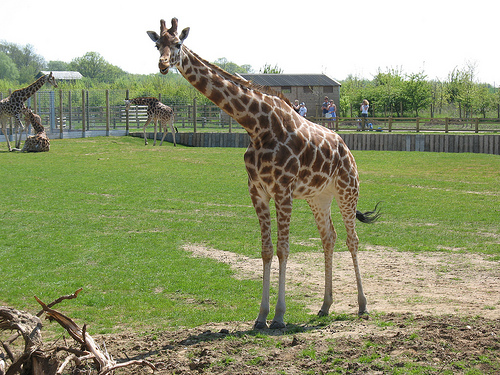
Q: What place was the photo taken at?
A: It was taken at the park.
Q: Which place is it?
A: It is a park.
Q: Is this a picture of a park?
A: Yes, it is showing a park.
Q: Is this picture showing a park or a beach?
A: It is showing a park.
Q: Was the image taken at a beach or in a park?
A: It was taken at a park.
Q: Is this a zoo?
A: No, it is a park.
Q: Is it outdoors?
A: Yes, it is outdoors.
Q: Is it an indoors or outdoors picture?
A: It is outdoors.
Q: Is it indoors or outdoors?
A: It is outdoors.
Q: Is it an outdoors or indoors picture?
A: It is outdoors.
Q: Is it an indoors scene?
A: No, it is outdoors.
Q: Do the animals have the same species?
A: Yes, all the animals are giraffes.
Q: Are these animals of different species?
A: No, all the animals are giraffes.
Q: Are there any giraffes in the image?
A: Yes, there is a giraffe.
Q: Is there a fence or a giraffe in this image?
A: Yes, there is a giraffe.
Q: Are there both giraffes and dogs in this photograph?
A: No, there is a giraffe but no dogs.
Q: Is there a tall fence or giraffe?
A: Yes, there is a tall giraffe.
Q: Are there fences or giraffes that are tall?
A: Yes, the giraffe is tall.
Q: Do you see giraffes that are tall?
A: Yes, there is a tall giraffe.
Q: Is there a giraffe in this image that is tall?
A: Yes, there is a giraffe that is tall.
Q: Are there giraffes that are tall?
A: Yes, there is a giraffe that is tall.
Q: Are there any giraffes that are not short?
A: Yes, there is a tall giraffe.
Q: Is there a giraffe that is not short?
A: Yes, there is a tall giraffe.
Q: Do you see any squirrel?
A: No, there are no squirrels.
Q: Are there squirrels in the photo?
A: No, there are no squirrels.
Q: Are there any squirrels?
A: No, there are no squirrels.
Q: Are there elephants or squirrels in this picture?
A: No, there are no squirrels or elephants.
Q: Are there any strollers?
A: No, there are no strollers.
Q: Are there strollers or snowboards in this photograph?
A: No, there are no strollers or snowboards.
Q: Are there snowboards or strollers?
A: No, there are no strollers or snowboards.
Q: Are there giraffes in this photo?
A: Yes, there is a giraffe.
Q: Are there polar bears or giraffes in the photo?
A: Yes, there is a giraffe.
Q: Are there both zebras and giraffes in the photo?
A: No, there is a giraffe but no zebras.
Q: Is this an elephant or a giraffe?
A: This is a giraffe.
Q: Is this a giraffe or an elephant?
A: This is a giraffe.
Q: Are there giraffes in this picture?
A: Yes, there are giraffes.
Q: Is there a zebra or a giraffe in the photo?
A: Yes, there are giraffes.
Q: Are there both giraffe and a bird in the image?
A: No, there are giraffes but no birds.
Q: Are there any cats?
A: No, there are no cats.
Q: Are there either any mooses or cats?
A: No, there are no cats or mooses.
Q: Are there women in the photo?
A: Yes, there is a woman.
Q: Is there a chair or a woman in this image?
A: Yes, there is a woman.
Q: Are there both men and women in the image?
A: No, there is a woman but no men.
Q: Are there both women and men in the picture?
A: No, there is a woman but no men.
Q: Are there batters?
A: No, there are no batters.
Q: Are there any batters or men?
A: No, there are no batters or men.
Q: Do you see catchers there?
A: No, there are no catchers.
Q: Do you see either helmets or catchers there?
A: No, there are no catchers or helmets.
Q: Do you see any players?
A: No, there are no players.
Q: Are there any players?
A: No, there are no players.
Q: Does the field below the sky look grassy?
A: Yes, the field is grassy.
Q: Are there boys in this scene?
A: No, there are no boys.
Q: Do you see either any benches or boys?
A: No, there are no boys or benches.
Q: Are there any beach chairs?
A: No, there are no beach chairs.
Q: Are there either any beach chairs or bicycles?
A: No, there are no beach chairs or bicycles.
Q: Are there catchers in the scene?
A: No, there are no catchers.